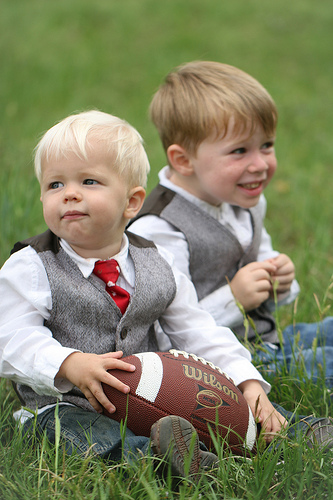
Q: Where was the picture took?
A: A lawn.